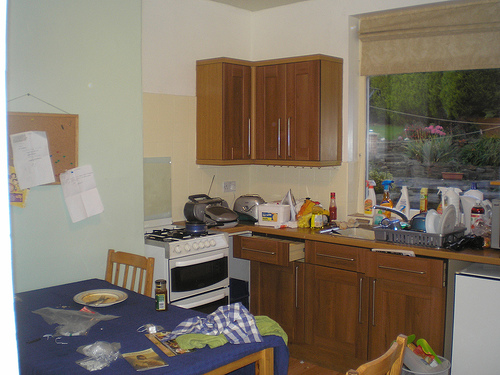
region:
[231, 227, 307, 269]
kitchen counter top drawer is open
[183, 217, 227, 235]
blue, silver, black pot atop gas range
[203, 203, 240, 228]
press type electric cooking grill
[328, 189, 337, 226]
hot sauce atop kitchen counter top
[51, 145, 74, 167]
unused push pins in cork boad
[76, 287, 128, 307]
2 utensils on plate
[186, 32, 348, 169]
kitchen cabinets in kitchen corner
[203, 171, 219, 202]
boombox radio antenna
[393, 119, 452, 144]
flowers in garden outside kitchen window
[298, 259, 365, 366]
kitchen cabinet door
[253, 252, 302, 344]
a wooden cupboard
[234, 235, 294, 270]
a wooden cupboard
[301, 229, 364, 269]
a wooden cupboard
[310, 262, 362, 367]
a wooden cupboard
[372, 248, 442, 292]
a wooden cupboard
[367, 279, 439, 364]
a wooden cupboard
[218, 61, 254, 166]
a wooden cupboard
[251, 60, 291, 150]
a wooden cupboard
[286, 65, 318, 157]
a wooden cupboard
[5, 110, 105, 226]
schedule on corkboard with colored pins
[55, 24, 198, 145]
bare walls, corner of the corkboard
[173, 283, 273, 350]
dish cloths on the table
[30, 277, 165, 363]
dirty dishes on the table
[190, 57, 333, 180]
brown cabinet hanging on kitchen wall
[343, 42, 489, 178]
window, plants and flowers outside, stone steps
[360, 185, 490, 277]
dish drain full of dishes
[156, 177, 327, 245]
messy counter top, radio, condiments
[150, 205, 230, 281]
oven with small frying pan on top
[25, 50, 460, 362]
messy, dirty kitchen with unkempt countertops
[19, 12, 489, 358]
Cluttered kitchen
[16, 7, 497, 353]
Kitchen in the house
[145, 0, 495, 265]
Kitchen to be cleaned soon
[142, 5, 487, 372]
Compact stove and dishwasher in the kitchen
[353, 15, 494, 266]
Cleaning supplies on the window sill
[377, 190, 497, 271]
Washed dishes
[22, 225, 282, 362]
Messy dining table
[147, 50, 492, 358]
Wooden kitchen cabinets with long pulls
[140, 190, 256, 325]
Stove with 2 ovens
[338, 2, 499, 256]
Window with rolling shade